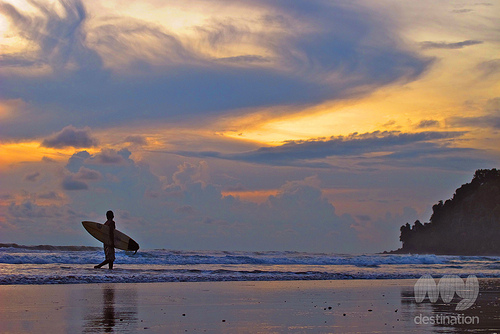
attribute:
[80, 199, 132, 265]
man — walking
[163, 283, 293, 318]
beach — wet, rocky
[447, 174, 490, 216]
trees — far, green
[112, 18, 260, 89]
clouds — shinning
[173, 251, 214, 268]
ocean — blue, covered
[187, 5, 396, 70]
sky — cloudy, colorful, bright, fluffy, blue, orange